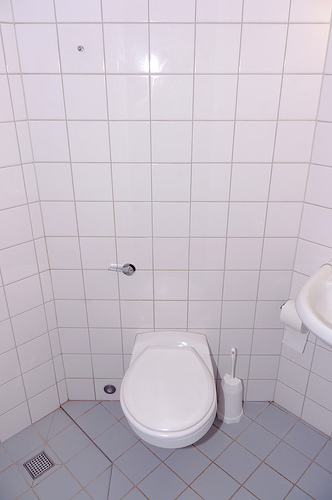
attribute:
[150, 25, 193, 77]
tile — square, reflecting, blue, white, gray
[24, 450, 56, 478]
drain — square, silver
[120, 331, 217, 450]
toilet — closed, curved, clean, ceramic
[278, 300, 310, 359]
tp — white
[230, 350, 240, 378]
brush — upright, white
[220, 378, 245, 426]
holder — white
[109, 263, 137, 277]
handle — metal, chrome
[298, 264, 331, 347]
sink — white